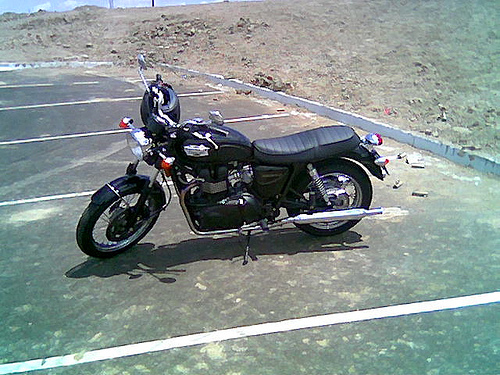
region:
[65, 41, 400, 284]
Small black motorcycle on pavement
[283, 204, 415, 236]
Long silver muffler on bike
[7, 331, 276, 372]
White line on pavement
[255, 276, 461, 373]
White line on pavement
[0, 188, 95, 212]
White line on pavement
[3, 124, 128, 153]
White line on pavement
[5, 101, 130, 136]
White line on pavement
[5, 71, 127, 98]
White line on pavement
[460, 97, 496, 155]
Small patch of brown dirt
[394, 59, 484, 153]
Small patch of brown dirt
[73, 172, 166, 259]
tire on the bike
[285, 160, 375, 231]
tire on the bike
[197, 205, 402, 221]
exhaust pipe on the bike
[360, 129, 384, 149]
tail light on the bike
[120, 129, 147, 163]
headlight on the bike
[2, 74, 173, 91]
line on the parking lot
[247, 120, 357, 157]
seat on the bike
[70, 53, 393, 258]
a black bike in the parking lot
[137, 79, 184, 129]
black helmet on the bike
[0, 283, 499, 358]
line on the parking lot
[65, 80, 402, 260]
Motorcycle in a parking spot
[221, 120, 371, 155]
Long, black seat on the motorcycle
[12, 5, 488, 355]
Photo taken during the day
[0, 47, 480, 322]
white lines in the parking lot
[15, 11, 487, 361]
Nobody in the photo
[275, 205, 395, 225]
Muffler to the motorcycle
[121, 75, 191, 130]
Helmet hanging on the motorcycle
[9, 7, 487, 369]
The weather is sunny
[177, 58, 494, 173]
The curb is white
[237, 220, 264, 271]
Motorcycle held up by kickstand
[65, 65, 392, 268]
black motorcycle in parking lot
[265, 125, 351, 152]
seat on the motorcycle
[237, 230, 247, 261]
the black bike's kickstand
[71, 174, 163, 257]
the black motorcycle's front tire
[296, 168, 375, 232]
black motorcycle's back tire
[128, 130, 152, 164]
the headlight on motorcycle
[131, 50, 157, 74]
right rearview mirror on bike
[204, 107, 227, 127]
left rearview mirror on bike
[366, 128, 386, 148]
motorcycle's red brake light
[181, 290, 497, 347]
white painted line in parking lot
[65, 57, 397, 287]
the motorbike is parked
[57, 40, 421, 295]
the motorbike is black